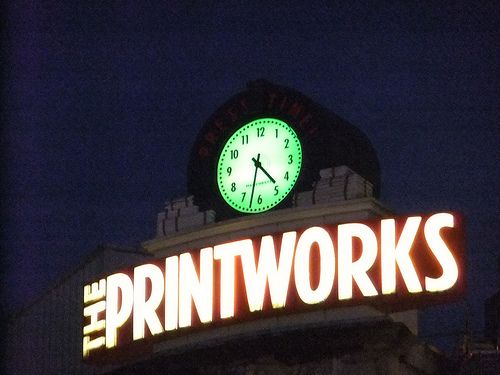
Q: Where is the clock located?
A: Above the sign.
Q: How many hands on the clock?
A: Two.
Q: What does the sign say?
A: The Printworks.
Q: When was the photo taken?
A: At night.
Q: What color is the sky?
A: Blue.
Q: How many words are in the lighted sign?
A: Two.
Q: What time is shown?
A: 4:32.